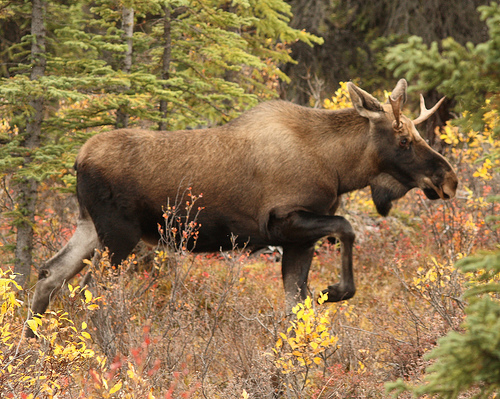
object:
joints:
[340, 217, 355, 243]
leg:
[282, 246, 315, 300]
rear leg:
[15, 201, 102, 351]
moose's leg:
[266, 209, 355, 281]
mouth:
[424, 177, 444, 199]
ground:
[0, 285, 499, 399]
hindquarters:
[78, 129, 127, 262]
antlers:
[412, 93, 446, 124]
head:
[348, 78, 458, 200]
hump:
[230, 100, 299, 122]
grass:
[0, 272, 93, 360]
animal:
[23, 78, 459, 337]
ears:
[347, 82, 384, 120]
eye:
[401, 138, 407, 144]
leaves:
[0, 0, 284, 189]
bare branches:
[137, 239, 163, 262]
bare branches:
[415, 287, 455, 328]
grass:
[272, 291, 337, 373]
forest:
[15, 0, 48, 289]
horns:
[389, 96, 403, 127]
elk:
[25, 78, 457, 337]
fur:
[172, 141, 264, 174]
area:
[0, 0, 499, 398]